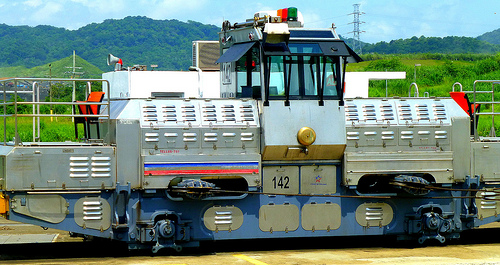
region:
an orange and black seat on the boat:
[69, 90, 106, 137]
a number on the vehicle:
[265, 167, 300, 194]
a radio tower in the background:
[349, 3, 366, 55]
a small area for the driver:
[233, 35, 345, 105]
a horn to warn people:
[103, 52, 120, 69]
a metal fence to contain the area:
[3, 80, 107, 145]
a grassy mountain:
[1, 25, 202, 63]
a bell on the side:
[296, 126, 318, 148]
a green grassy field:
[415, 55, 492, 92]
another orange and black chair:
[445, 91, 479, 129]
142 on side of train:
[248, 164, 310, 204]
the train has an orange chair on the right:
[55, 78, 135, 149]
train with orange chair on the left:
[42, 88, 117, 144]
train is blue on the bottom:
[135, 188, 475, 244]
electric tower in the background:
[345, 8, 380, 58]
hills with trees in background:
[10, 30, 180, 91]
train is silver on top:
[100, 73, 480, 174]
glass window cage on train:
[225, 20, 361, 115]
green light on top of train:
[287, 1, 308, 14]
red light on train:
[281, 2, 298, 16]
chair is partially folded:
[70, 89, 109, 142]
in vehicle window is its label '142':
[221, 60, 233, 85]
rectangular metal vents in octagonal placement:
[71, 192, 116, 233]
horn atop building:
[103, 50, 125, 74]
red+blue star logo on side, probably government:
[307, 172, 328, 187]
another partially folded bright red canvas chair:
[448, 88, 484, 136]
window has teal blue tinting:
[265, 53, 342, 97]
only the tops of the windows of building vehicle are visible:
[98, 68, 408, 98]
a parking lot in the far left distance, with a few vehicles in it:
[0, 75, 62, 106]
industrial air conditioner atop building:
[188, 39, 223, 71]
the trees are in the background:
[66, 30, 183, 61]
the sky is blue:
[48, 2, 226, 15]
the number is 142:
[263, 174, 299, 193]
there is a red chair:
[75, 83, 116, 150]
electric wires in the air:
[353, 8, 450, 32]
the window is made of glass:
[235, 55, 350, 99]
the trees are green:
[436, 55, 489, 75]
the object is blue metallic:
[152, 202, 197, 239]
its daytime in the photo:
[1, 2, 493, 257]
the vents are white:
[139, 107, 251, 122]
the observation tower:
[217, 10, 352, 262]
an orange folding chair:
[64, 82, 110, 142]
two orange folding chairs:
[59, 89, 499, 136]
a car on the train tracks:
[3, 6, 493, 261]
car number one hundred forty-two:
[11, 7, 493, 257]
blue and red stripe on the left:
[117, 98, 472, 189]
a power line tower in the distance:
[341, 0, 376, 70]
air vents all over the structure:
[1, 36, 498, 243]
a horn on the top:
[96, 24, 129, 99]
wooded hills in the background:
[4, 3, 496, 68]